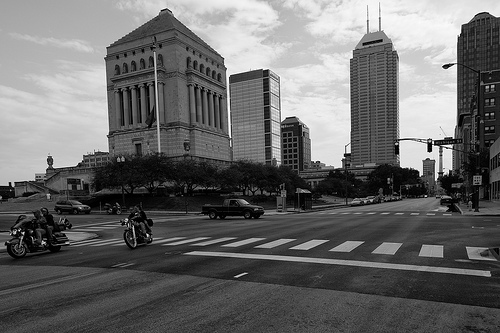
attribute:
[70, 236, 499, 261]
crosswalk — white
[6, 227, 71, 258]
motorcycle — tandem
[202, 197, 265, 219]
truck — driving, moving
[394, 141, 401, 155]
traffic light — hanging, overhead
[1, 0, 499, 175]
sky — cloudy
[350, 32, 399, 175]
building — tall, skyscraper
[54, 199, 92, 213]
suv — parked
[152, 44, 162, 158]
flag pole — white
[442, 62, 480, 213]
street light — tall, modern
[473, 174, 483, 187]
street sign — one way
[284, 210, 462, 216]
crosswalk — white